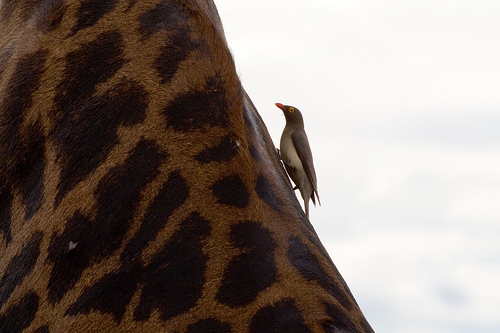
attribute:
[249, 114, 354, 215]
feathers — tail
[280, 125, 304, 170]
grey underbelly — soft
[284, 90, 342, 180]
bird — small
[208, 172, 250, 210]
spot — black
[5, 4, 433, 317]
bird — yellow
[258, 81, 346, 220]
bird — small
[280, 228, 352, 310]
spot — black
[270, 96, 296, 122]
beak — red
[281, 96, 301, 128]
eye — yellow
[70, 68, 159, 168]
fur — fluffed, tussled, messy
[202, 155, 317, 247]
area — balding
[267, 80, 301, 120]
beak — orange